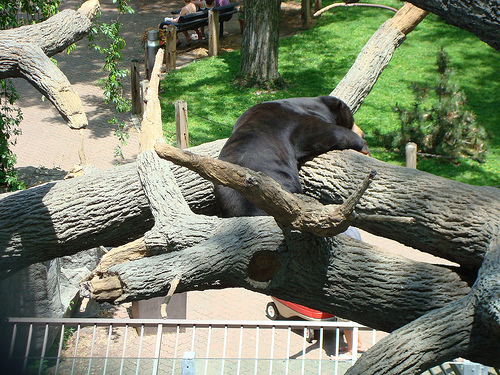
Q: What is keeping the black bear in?
A: The fence.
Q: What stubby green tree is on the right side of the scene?
A: Pine tree.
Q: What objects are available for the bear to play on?
A: Giant fake logs.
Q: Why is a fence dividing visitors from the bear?
A: For safety.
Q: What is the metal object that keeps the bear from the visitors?
A: Fence railing.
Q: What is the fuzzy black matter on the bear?
A: Fur.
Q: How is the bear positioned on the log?
A: Lying belly down.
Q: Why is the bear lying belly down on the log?
A: Sleeping.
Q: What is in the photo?
A: An animal.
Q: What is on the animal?
A: Fur.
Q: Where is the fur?
A: On the animal.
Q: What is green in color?
A: The grass.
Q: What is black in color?
A: The animal.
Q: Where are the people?
A: On a bench.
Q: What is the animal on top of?
A: A tree trunk.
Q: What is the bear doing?
A: Resting.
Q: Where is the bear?
A: In the tree.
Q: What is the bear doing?
A: Sleeping.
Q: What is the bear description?
A: Black.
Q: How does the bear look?
A: Black.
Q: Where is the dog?
A: On the tree.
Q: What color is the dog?
A: Black.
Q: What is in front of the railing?
A: Toy car.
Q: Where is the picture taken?
A: Park.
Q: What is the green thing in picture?
A: Lawn.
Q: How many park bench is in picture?
A: One.